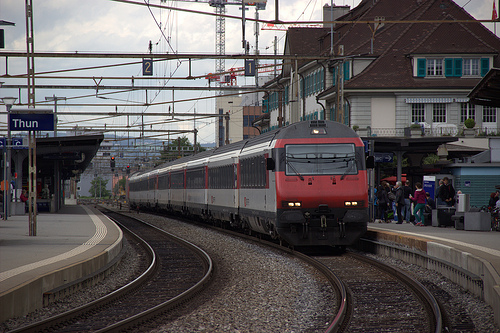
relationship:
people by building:
[377, 171, 453, 231] [257, 0, 498, 218]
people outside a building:
[366, 176, 460, 224] [250, 0, 499, 172]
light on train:
[282, 199, 303, 209] [120, 115, 373, 258]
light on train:
[338, 195, 361, 207] [120, 115, 373, 258]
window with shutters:
[424, 55, 444, 77] [413, 56, 427, 77]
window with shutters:
[460, 57, 481, 77] [442, 55, 464, 80]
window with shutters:
[424, 55, 444, 77] [479, 55, 491, 78]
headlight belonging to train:
[283, 198, 303, 210] [102, 123, 372, 254]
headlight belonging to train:
[339, 197, 364, 209] [102, 123, 372, 254]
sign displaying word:
[4, 110, 61, 130] [12, 114, 48, 132]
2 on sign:
[144, 61, 151, 72] [142, 58, 154, 75]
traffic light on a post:
[109, 153, 115, 175] [89, 151, 151, 166]